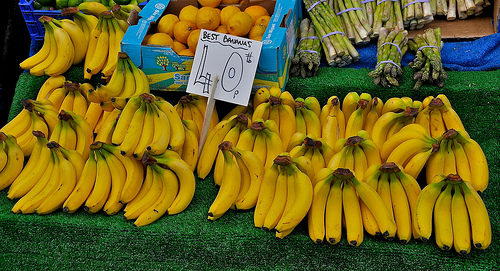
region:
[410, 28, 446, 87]
vegetables in a bundle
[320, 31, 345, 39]
blue bands on the vegetables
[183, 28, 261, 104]
white sign with a price on it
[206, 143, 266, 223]
bundle of bananas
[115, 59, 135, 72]
green stem on the banana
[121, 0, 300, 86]
a blue cardboard box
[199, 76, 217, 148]
small wooden stick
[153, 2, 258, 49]
pile of oranges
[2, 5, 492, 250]
table of bananas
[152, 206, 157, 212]
brown spot on the banana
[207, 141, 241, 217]
banana is next to banana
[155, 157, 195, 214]
banana is next to banana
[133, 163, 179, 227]
banana is next to banana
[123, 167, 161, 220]
banana is next to banana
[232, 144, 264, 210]
banana is next to banana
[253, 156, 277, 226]
banana is next to banana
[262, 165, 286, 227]
banana is next to banana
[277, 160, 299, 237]
banana is next to banana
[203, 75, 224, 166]
The stick holding the sign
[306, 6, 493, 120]
The green asparagus in the back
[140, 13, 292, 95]
A blue cardboard box on the counter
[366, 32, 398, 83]
rubber-bands holding the asparagus toghether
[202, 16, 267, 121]
The sign with the price on it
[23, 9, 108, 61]
The blue milk crate behind them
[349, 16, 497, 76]
The blue tarp under the asparagus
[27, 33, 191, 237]
The bananas on the left of the sing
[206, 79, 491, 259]
The bananas on the right of the sign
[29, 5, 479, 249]
Fruit and veggies being sold at a stand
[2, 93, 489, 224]
bundles of ripe bananas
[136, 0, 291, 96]
box or oranges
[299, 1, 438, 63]
bundles of asparagus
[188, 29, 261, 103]
the bananas are 40 cents per pound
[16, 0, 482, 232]
fruits and veggies and the grocery store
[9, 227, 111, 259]
fuzzy green material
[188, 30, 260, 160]
a sign with the price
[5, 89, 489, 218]
lots of bananas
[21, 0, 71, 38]
box of limes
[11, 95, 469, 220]
many bananas with lots of potassium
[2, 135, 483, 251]
a row of bananas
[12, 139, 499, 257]
a row of bananas on a green grass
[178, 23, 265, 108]
a white and black sign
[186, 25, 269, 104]
a sign with a number on it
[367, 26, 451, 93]
a bundle of green vegetables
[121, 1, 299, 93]
a box of oranges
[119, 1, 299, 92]
a blue box of oranges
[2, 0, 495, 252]
fruits and vegetables on a stand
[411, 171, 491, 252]
a bunch of bananas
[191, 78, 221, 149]
a wooden stick on a sign